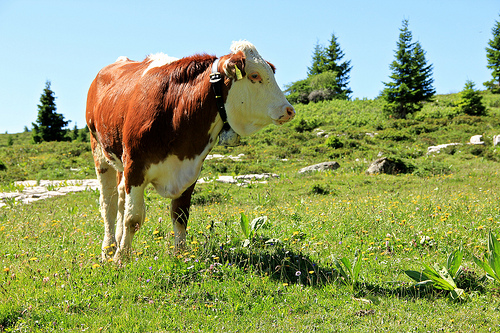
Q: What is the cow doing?
A: Standing in a field.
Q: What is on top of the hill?
A: Trees.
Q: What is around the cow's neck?
A: A collar.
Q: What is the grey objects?
A: Big rocks.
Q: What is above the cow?
A: The sky.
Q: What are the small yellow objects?
A: Flowers.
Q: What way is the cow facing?
A: To the right.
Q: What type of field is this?
A: A grassy field.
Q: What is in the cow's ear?
A: A tag.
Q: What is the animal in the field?
A: A cow.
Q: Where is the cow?
A: In the grass.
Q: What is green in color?
A: Grass.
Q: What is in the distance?
A: Trees.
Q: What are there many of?
A: Trees.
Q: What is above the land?
A: The sky.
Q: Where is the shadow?
A: On the ground.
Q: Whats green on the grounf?
A: Grass.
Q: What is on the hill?
A: Rocks.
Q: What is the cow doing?
A: Standing.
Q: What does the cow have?
A: White face.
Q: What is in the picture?
A: A cow is in the picture.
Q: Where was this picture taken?
A: It was taken in the field.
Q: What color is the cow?
A: The cow is brown and white.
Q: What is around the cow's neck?
A: A collar is around the cows neck.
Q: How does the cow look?
A: The cow looks healthy.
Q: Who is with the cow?
A: Nobody is with the cow.